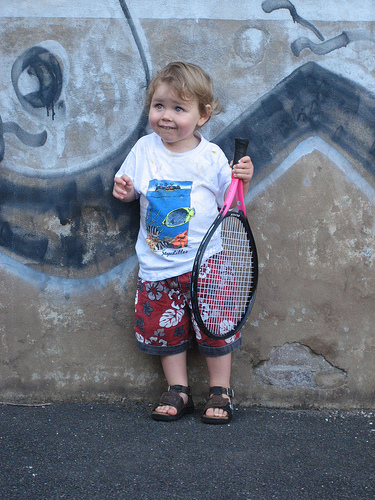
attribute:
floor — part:
[3, 408, 370, 498]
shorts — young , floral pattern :
[126, 260, 269, 370]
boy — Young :
[93, 49, 255, 495]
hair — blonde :
[126, 49, 231, 121]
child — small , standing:
[112, 61, 253, 425]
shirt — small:
[113, 129, 231, 282]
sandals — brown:
[202, 385, 237, 420]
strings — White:
[222, 257, 239, 289]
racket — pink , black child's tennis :
[196, 107, 271, 356]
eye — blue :
[171, 102, 192, 113]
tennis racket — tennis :
[187, 131, 260, 345]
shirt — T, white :
[125, 138, 226, 274]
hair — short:
[143, 60, 223, 116]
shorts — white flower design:
[132, 247, 244, 358]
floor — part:
[230, 411, 350, 494]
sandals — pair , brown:
[148, 382, 240, 425]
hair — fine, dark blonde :
[137, 61, 217, 121]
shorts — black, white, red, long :
[136, 245, 252, 360]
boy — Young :
[104, 49, 316, 459]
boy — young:
[100, 83, 255, 371]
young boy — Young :
[107, 48, 280, 433]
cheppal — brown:
[144, 383, 237, 425]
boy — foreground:
[69, 61, 301, 430]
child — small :
[101, 58, 263, 430]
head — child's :
[143, 58, 219, 148]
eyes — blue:
[150, 98, 186, 111]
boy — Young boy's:
[97, 51, 264, 427]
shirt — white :
[114, 130, 253, 284]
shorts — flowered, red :
[132, 255, 247, 361]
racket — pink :
[187, 130, 262, 340]